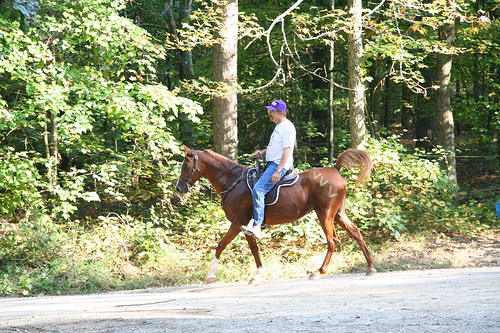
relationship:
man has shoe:
[240, 99, 298, 241] [241, 223, 263, 239]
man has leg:
[240, 99, 298, 241] [252, 161, 290, 228]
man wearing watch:
[240, 99, 298, 241] [275, 167, 283, 174]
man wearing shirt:
[240, 99, 298, 241] [266, 119, 296, 170]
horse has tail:
[176, 148, 382, 283] [334, 146, 375, 195]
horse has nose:
[176, 148, 382, 283] [173, 182, 189, 196]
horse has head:
[176, 148, 382, 283] [174, 148, 202, 197]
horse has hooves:
[176, 148, 382, 283] [204, 265, 377, 287]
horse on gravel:
[176, 148, 382, 283] [2, 265, 498, 332]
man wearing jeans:
[240, 99, 298, 241] [251, 160, 292, 226]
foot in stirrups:
[240, 221, 264, 239] [241, 215, 256, 234]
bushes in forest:
[290, 138, 493, 242] [1, 1, 497, 249]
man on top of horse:
[240, 99, 298, 241] [176, 148, 382, 283]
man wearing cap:
[240, 99, 298, 241] [265, 97, 289, 116]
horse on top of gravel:
[176, 148, 382, 283] [2, 265, 498, 332]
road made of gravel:
[0, 266, 499, 332] [2, 265, 498, 332]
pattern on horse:
[313, 167, 339, 206] [176, 148, 382, 283]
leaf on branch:
[199, 75, 211, 82] [183, 40, 288, 94]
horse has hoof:
[176, 148, 382, 283] [202, 257, 220, 285]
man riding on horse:
[240, 99, 298, 241] [176, 148, 382, 283]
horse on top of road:
[176, 148, 382, 283] [0, 266, 499, 332]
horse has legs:
[176, 148, 382, 283] [207, 211, 377, 286]